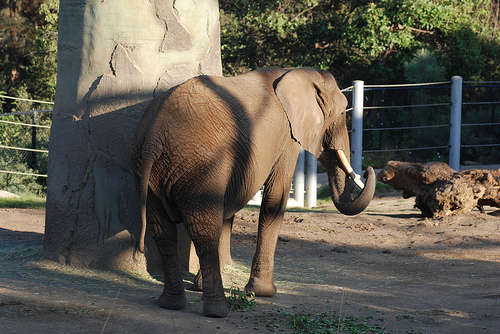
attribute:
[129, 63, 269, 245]
elephant — brown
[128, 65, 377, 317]
elephant — brown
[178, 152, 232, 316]
leg — brown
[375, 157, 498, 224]
tree trunk — wooden 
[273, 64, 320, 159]
ear — big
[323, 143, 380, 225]
trunk — brown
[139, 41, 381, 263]
elephant — brown